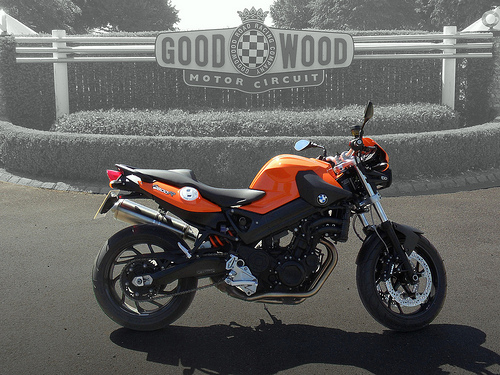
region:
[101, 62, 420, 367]
a black and orange motorbike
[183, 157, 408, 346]
a black and orange motorbike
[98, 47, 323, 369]
a black and orange motorbike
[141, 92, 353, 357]
a black and orange motorbike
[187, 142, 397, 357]
a black and orange motorbike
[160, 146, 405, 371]
a black and orange motorbike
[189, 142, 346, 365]
a black and orange motorbike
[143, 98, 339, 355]
a black and orange motorbike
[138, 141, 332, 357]
a black and orange motorbike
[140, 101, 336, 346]
a black and orange motorbike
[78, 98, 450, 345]
The motorcycle is black and orange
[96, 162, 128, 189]
Brake light on back of motorcycle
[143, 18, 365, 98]
Sign says Good Wood Motor Circuit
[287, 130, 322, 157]
Rear view mirror on motorcycle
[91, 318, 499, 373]
Shadow of motorcycle on pavement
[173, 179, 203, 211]
Gas tank on motorcycle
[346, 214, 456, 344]
Front wheel on motorcycle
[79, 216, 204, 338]
Rear wheel on motorcycle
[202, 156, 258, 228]
Driver's seat on motorcycle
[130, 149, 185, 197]
Passenger seat on motorcycle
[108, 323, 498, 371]
shadow cast on street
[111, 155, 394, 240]
bike is orange and black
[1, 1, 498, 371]
bike is only thing in color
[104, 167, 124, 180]
tail light on back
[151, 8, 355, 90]
sign says good wood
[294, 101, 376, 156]
bike has two mirrors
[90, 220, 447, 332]
bike has two tires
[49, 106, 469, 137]
hedge bush under sign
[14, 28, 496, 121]
sign is hung on poles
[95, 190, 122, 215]
license plate on back of bike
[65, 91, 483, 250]
the bike is orange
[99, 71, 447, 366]
the bike is orange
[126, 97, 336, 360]
the bike is orange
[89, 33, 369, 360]
the bike is orange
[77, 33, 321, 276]
the bike is orange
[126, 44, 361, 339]
the bike is orange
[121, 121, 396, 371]
the bike is orange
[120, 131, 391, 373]
the bike is orange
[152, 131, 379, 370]
the bike is orange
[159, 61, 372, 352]
the bike is orange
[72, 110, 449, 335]
The bike is orange and black.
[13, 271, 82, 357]
The ground is black.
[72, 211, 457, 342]
The tires are black.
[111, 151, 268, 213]
The seat is black.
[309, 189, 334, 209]
The bike is made by BMW.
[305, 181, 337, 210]
A BMW logo is on the bike.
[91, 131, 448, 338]
The bike is glossy.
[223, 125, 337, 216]
The gas tank is orange.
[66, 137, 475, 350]
The bike is not being used.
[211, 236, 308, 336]
The bike is propped up.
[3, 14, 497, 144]
a fence in the background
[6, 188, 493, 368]
a concrete pavement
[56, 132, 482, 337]
motorcycle in the background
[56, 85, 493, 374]
orange motorcycle in the background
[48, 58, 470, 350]
motorcycle parked in the background